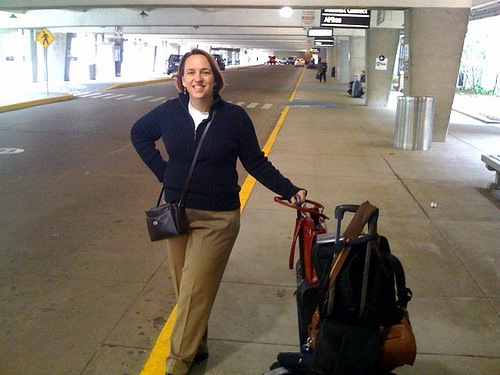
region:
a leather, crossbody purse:
[126, 94, 223, 244]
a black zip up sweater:
[130, 88, 307, 228]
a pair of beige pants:
[153, 198, 240, 374]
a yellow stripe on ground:
[269, 104, 286, 159]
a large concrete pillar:
[362, 25, 402, 108]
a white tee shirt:
[185, 97, 215, 132]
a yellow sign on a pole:
[33, 26, 56, 95]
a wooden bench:
[480, 151, 499, 198]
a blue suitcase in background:
[350, 71, 362, 97]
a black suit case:
[287, 201, 412, 368]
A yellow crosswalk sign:
[32, 24, 60, 98]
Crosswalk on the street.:
[83, 89, 153, 105]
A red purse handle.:
[272, 182, 328, 224]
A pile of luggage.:
[273, 185, 427, 373]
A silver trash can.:
[392, 88, 436, 154]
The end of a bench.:
[481, 147, 499, 189]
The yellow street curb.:
[136, 297, 173, 372]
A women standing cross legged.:
[132, 37, 300, 374]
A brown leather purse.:
[131, 192, 196, 246]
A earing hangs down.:
[181, 84, 187, 95]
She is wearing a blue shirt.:
[115, 43, 285, 243]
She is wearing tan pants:
[114, 48, 251, 370]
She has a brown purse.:
[83, 38, 325, 290]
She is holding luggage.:
[130, 42, 430, 357]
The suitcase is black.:
[274, 178, 426, 374]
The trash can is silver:
[375, 79, 445, 176]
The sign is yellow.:
[23, 23, 65, 62]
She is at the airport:
[17, 18, 496, 371]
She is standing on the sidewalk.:
[93, 40, 445, 373]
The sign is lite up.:
[320, 6, 385, 56]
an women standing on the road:
[124, 38, 306, 360]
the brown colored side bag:
[134, 172, 196, 244]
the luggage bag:
[273, 178, 426, 364]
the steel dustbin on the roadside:
[389, 74, 450, 159]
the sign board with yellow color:
[32, 24, 69, 104]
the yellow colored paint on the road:
[267, 101, 287, 156]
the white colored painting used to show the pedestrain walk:
[75, 80, 141, 110]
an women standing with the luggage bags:
[119, 39, 436, 367]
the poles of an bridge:
[360, 14, 405, 114]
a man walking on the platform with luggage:
[310, 56, 330, 91]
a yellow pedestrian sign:
[27, 30, 67, 56]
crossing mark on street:
[78, 91, 135, 106]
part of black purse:
[146, 196, 186, 240]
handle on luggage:
[335, 197, 384, 239]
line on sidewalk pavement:
[385, 161, 423, 201]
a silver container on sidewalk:
[396, 90, 434, 154]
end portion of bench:
[469, 146, 499, 176]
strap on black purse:
[188, 138, 212, 178]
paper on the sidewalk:
[424, 189, 452, 219]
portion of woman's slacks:
[201, 232, 218, 283]